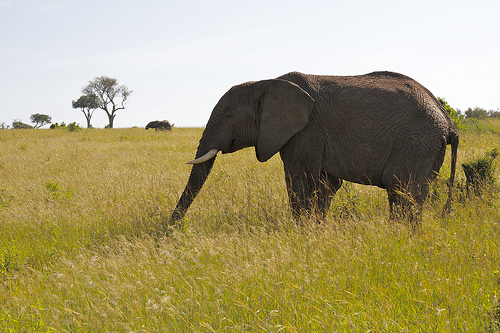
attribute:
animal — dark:
[136, 100, 178, 130]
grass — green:
[23, 203, 447, 330]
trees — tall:
[58, 77, 144, 134]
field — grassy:
[63, 121, 158, 285]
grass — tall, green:
[2, 121, 497, 328]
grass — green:
[134, 206, 494, 302]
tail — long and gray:
[445, 133, 460, 219]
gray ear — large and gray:
[242, 76, 319, 166]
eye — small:
[223, 110, 231, 120]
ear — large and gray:
[256, 80, 313, 164]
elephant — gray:
[160, 67, 467, 243]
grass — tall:
[345, 185, 477, 290]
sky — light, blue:
[3, 53, 498, 133]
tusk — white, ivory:
[185, 144, 226, 182]